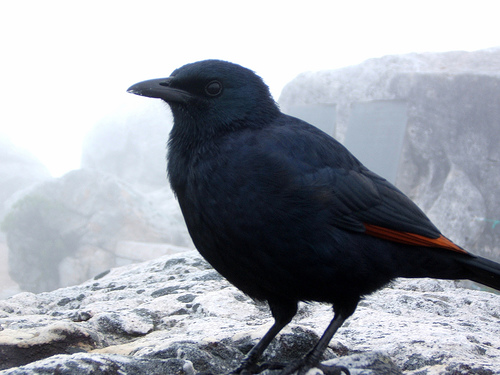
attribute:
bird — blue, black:
[109, 66, 497, 333]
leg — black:
[282, 296, 363, 371]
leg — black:
[221, 300, 296, 372]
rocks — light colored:
[15, 264, 497, 371]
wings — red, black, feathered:
[313, 162, 481, 257]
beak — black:
[113, 70, 185, 101]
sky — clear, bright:
[0, 0, 498, 49]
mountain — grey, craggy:
[284, 48, 495, 260]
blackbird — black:
[44, 28, 499, 353]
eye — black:
[192, 55, 270, 115]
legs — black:
[223, 292, 391, 373]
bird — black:
[126, 45, 429, 315]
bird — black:
[111, 46, 458, 364]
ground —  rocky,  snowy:
[6, 247, 495, 374]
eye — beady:
[203, 82, 223, 97]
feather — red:
[361, 224, 446, 249]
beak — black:
[128, 81, 190, 99]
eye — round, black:
[209, 86, 246, 121]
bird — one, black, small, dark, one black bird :
[115, 57, 494, 374]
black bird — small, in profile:
[125, 60, 498, 373]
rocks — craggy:
[0, 45, 500, 374]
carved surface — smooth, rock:
[342, 92, 407, 180]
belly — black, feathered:
[179, 195, 267, 304]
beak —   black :
[125, 77, 192, 105]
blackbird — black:
[110, 67, 375, 279]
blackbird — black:
[117, 93, 367, 277]